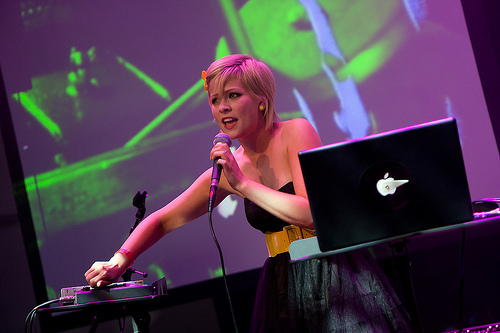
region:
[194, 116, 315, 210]
The lady is hlding a microphone.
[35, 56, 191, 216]
The screen has green grafitti.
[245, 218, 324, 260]
The woman is wearing a yellow belt.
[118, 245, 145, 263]
The woman is wearing a red ban on wrist.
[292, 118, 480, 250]
An opened Apple laptop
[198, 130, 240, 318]
A microphone and attached cord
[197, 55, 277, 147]
A woman with short cropped blonde hair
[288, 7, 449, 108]
An abstract colorful background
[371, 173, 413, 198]
The Apple logo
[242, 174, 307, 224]
A bare human arm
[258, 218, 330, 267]
A wide yellow belt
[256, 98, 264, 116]
A bright yellow earring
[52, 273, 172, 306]
A gray small mixing board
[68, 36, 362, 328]
this is a woman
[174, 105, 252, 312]
this is a microphone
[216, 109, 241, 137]
woman has mouth open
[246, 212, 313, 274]
woman wearing a yellow belt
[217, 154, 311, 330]
woman wearing a black dress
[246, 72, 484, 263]
this is a computer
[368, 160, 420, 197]
apple on the computer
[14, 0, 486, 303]
projection screen in background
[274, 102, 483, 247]
an open apple laptop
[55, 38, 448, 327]
a woman on a microphone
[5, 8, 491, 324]
a projection screen in the background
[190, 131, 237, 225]
a microphone in a woman's hand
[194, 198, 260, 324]
a microphone cord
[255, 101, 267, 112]
a yellow earring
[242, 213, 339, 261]
a bright yellow belt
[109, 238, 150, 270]
a woman's bracelet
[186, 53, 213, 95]
an orange hair clip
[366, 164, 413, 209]
an apple logo on a computer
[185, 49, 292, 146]
head of a girl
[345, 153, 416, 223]
logo on back of computer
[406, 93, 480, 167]
corner of the computer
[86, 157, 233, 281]
arm of the girl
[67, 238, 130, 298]
hand of the girl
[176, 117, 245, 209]
microphone in girl's hand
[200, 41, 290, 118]
blonde hair on girl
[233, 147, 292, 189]
shadow on girl's chest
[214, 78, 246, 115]
eye of the girl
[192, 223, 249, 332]
cord of the microphone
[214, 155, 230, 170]
white human female finger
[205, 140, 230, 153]
white human female finger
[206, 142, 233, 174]
white human female fingers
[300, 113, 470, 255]
a laptop is next to the woman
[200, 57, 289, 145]
the woman has short hair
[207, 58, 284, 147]
the woman is a blonde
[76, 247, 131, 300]
the woman is turning a dial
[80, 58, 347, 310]
the woman is a dee jay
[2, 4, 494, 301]
a projection screen is in the background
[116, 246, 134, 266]
the woman is wearing a wrist band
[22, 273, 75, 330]
a cable is coming out of the machine